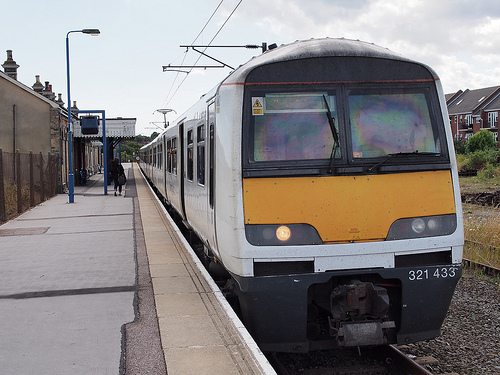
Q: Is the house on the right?
A: Yes, the house is on the right of the image.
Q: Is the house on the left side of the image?
A: No, the house is on the right of the image.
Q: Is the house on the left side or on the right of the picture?
A: The house is on the right of the image.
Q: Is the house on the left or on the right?
A: The house is on the right of the image.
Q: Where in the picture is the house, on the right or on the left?
A: The house is on the right of the image.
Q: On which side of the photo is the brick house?
A: The house is on the right of the image.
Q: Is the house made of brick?
A: Yes, the house is made of brick.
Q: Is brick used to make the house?
A: Yes, the house is made of brick.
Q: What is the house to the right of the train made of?
A: The house is made of brick.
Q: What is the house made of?
A: The house is made of brick.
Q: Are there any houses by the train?
A: Yes, there is a house by the train.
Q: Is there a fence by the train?
A: No, there is a house by the train.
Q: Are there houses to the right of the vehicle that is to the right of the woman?
A: Yes, there is a house to the right of the train.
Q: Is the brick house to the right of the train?
A: Yes, the house is to the right of the train.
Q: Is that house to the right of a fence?
A: No, the house is to the right of the train.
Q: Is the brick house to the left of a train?
A: No, the house is to the right of a train.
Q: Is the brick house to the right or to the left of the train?
A: The house is to the right of the train.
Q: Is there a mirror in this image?
A: No, there are no mirrors.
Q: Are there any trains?
A: Yes, there is a train.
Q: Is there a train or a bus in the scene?
A: Yes, there is a train.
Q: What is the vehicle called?
A: The vehicle is a train.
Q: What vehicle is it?
A: The vehicle is a train.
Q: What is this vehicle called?
A: This is a train.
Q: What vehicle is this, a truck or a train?
A: This is a train.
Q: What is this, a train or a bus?
A: This is a train.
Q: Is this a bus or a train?
A: This is a train.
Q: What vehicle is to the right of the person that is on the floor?
A: The vehicle is a train.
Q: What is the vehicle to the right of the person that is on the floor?
A: The vehicle is a train.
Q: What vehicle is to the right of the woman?
A: The vehicle is a train.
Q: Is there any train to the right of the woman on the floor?
A: Yes, there is a train to the right of the woman.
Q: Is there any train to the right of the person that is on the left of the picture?
A: Yes, there is a train to the right of the woman.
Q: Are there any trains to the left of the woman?
A: No, the train is to the right of the woman.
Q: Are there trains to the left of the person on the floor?
A: No, the train is to the right of the woman.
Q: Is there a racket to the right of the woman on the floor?
A: No, there is a train to the right of the woman.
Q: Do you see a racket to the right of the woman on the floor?
A: No, there is a train to the right of the woman.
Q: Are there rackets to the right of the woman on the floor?
A: No, there is a train to the right of the woman.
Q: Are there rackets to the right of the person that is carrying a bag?
A: No, there is a train to the right of the woman.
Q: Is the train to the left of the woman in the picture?
A: No, the train is to the right of the woman.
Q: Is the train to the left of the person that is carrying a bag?
A: No, the train is to the right of the woman.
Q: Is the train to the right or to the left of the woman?
A: The train is to the right of the woman.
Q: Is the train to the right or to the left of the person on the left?
A: The train is to the right of the woman.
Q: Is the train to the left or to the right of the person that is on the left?
A: The train is to the right of the woman.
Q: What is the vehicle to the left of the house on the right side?
A: The vehicle is a train.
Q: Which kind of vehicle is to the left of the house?
A: The vehicle is a train.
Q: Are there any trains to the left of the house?
A: Yes, there is a train to the left of the house.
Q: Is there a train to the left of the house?
A: Yes, there is a train to the left of the house.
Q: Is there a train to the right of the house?
A: No, the train is to the left of the house.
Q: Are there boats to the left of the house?
A: No, there is a train to the left of the house.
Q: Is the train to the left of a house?
A: Yes, the train is to the left of a house.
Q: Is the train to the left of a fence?
A: No, the train is to the left of a house.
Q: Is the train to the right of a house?
A: No, the train is to the left of a house.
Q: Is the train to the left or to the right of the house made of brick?
A: The train is to the left of the house.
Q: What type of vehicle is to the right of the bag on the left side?
A: The vehicle is a train.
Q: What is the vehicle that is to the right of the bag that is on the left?
A: The vehicle is a train.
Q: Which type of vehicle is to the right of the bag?
A: The vehicle is a train.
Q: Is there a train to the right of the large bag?
A: Yes, there is a train to the right of the bag.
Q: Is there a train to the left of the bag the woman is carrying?
A: No, the train is to the right of the bag.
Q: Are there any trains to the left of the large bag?
A: No, the train is to the right of the bag.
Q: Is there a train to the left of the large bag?
A: No, the train is to the right of the bag.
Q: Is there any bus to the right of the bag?
A: No, there is a train to the right of the bag.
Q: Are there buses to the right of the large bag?
A: No, there is a train to the right of the bag.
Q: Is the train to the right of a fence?
A: No, the train is to the right of the bag.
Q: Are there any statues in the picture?
A: No, there are no statues.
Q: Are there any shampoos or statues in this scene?
A: No, there are no statues or shampoos.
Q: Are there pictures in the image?
A: No, there are no pictures.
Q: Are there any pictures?
A: No, there are no pictures.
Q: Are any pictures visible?
A: No, there are no pictures.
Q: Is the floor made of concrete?
A: Yes, the floor is made of concrete.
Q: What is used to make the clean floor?
A: The floor is made of concrete.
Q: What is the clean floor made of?
A: The floor is made of concrete.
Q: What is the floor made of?
A: The floor is made of concrete.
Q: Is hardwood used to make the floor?
A: No, the floor is made of cement.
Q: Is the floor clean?
A: Yes, the floor is clean.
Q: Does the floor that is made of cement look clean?
A: Yes, the floor is clean.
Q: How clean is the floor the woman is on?
A: The floor is clean.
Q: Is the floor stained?
A: No, the floor is clean.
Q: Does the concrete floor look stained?
A: No, the floor is clean.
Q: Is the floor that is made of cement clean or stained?
A: The floor is clean.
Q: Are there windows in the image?
A: Yes, there is a window.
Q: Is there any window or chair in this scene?
A: Yes, there is a window.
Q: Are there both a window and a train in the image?
A: Yes, there are both a window and a train.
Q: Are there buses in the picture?
A: No, there are no buses.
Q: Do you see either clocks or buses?
A: No, there are no buses or clocks.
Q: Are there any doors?
A: Yes, there is a door.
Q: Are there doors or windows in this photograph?
A: Yes, there is a door.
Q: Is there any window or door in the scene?
A: Yes, there is a door.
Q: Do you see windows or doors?
A: Yes, there is a door.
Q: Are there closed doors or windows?
A: Yes, there is a closed door.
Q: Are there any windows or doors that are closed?
A: Yes, the door is closed.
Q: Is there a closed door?
A: Yes, there is a closed door.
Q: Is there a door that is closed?
A: Yes, there is a door that is closed.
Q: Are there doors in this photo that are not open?
A: Yes, there is an closed door.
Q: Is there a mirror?
A: No, there are no mirrors.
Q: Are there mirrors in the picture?
A: No, there are no mirrors.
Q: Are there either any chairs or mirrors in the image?
A: No, there are no mirrors or chairs.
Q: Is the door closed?
A: Yes, the door is closed.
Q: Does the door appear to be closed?
A: Yes, the door is closed.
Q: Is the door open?
A: No, the door is closed.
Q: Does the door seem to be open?
A: No, the door is closed.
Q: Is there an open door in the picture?
A: No, there is a door but it is closed.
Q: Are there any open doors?
A: No, there is a door but it is closed.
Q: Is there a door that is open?
A: No, there is a door but it is closed.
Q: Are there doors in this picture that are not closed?
A: No, there is a door but it is closed.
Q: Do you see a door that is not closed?
A: No, there is a door but it is closed.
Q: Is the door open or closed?
A: The door is closed.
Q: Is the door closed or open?
A: The door is closed.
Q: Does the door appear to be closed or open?
A: The door is closed.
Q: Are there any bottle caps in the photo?
A: No, there are no bottle caps.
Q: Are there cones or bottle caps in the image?
A: No, there are no bottle caps or cones.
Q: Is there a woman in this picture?
A: Yes, there is a woman.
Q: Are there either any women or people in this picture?
A: Yes, there is a woman.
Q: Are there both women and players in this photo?
A: No, there is a woman but no players.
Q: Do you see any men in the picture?
A: No, there are no men.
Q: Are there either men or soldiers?
A: No, there are no men or soldiers.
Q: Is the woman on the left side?
A: Yes, the woman is on the left of the image.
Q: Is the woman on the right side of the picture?
A: No, the woman is on the left of the image.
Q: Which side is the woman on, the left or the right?
A: The woman is on the left of the image.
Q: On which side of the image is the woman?
A: The woman is on the left of the image.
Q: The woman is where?
A: The woman is on the floor.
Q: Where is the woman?
A: The woman is on the floor.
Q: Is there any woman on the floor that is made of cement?
A: Yes, there is a woman on the floor.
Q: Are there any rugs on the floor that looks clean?
A: No, there is a woman on the floor.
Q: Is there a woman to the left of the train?
A: Yes, there is a woman to the left of the train.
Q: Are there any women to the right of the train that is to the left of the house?
A: No, the woman is to the left of the train.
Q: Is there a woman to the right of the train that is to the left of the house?
A: No, the woman is to the left of the train.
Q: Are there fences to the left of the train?
A: No, there is a woman to the left of the train.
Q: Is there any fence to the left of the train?
A: No, there is a woman to the left of the train.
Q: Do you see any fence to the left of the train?
A: No, there is a woman to the left of the train.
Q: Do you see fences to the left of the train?
A: No, there is a woman to the left of the train.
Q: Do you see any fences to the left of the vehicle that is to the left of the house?
A: No, there is a woman to the left of the train.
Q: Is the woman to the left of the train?
A: Yes, the woman is to the left of the train.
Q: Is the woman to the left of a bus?
A: No, the woman is to the left of the train.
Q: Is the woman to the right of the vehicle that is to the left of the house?
A: No, the woman is to the left of the train.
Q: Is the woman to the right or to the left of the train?
A: The woman is to the left of the train.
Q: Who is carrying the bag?
A: The woman is carrying the bag.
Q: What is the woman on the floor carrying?
A: The woman is carrying a bag.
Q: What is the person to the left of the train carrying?
A: The woman is carrying a bag.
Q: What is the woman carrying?
A: The woman is carrying a bag.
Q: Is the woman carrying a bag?
A: Yes, the woman is carrying a bag.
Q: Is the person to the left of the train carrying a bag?
A: Yes, the woman is carrying a bag.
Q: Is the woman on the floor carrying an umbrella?
A: No, the woman is carrying a bag.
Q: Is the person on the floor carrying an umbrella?
A: No, the woman is carrying a bag.